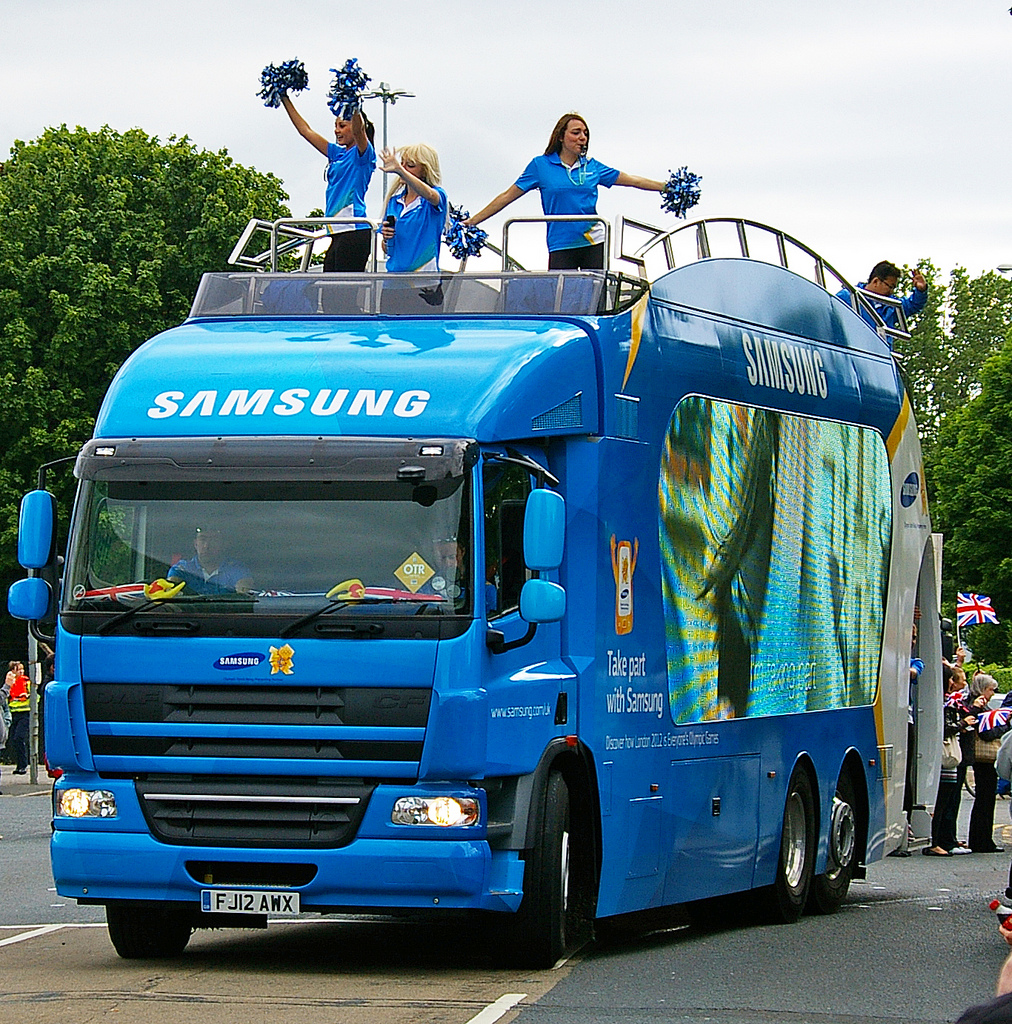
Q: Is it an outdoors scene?
A: Yes, it is outdoors.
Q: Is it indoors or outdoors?
A: It is outdoors.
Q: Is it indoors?
A: No, it is outdoors.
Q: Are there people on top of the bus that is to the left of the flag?
A: Yes, there is a person on top of the bus.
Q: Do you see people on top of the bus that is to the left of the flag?
A: Yes, there is a person on top of the bus.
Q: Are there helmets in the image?
A: No, there are no helmets.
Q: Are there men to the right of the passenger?
A: Yes, there is a man to the right of the passenger.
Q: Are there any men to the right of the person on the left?
A: Yes, there is a man to the right of the passenger.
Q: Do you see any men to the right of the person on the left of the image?
A: Yes, there is a man to the right of the passenger.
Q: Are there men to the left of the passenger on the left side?
A: No, the man is to the right of the passenger.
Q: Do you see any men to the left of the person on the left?
A: No, the man is to the right of the passenger.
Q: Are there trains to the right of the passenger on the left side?
A: No, there is a man to the right of the passenger.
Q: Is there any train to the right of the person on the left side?
A: No, there is a man to the right of the passenger.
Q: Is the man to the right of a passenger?
A: Yes, the man is to the right of a passenger.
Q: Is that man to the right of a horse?
A: No, the man is to the right of a passenger.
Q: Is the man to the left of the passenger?
A: No, the man is to the right of the passenger.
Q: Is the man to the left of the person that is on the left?
A: No, the man is to the right of the passenger.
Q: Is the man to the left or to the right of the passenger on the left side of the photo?
A: The man is to the right of the passenger.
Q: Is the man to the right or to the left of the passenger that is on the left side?
A: The man is to the right of the passenger.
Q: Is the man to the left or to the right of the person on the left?
A: The man is to the right of the passenger.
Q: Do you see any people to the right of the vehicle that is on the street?
A: Yes, there is a person to the right of the bus.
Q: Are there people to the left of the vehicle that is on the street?
A: No, the person is to the right of the bus.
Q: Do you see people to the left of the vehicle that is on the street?
A: No, the person is to the right of the bus.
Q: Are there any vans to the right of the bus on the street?
A: No, there is a person to the right of the bus.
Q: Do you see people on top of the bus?
A: Yes, there is a person on top of the bus.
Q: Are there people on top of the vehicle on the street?
A: Yes, there is a person on top of the bus.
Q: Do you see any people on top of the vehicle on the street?
A: Yes, there is a person on top of the bus.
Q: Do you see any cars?
A: No, there are no cars.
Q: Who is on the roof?
A: The people are on the roof.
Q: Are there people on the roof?
A: Yes, there are people on the roof.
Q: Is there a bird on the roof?
A: No, there are people on the roof.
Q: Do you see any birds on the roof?
A: No, there are people on the roof.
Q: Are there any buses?
A: Yes, there is a bus.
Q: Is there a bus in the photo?
A: Yes, there is a bus.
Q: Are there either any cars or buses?
A: Yes, there is a bus.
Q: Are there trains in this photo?
A: No, there are no trains.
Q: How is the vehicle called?
A: The vehicle is a bus.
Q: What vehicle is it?
A: The vehicle is a bus.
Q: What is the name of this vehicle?
A: This is a bus.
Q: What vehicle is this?
A: This is a bus.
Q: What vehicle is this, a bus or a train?
A: This is a bus.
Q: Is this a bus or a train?
A: This is a bus.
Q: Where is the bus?
A: The bus is on the street.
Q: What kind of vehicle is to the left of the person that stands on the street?
A: The vehicle is a bus.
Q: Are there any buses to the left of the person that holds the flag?
A: Yes, there is a bus to the left of the person.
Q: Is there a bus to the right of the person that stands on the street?
A: No, the bus is to the left of the person.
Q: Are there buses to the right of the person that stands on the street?
A: No, the bus is to the left of the person.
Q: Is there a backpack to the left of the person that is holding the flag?
A: No, there is a bus to the left of the person.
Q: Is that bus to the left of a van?
A: No, the bus is to the left of a person.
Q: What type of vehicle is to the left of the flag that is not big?
A: The vehicle is a bus.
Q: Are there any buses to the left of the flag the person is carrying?
A: Yes, there is a bus to the left of the flag.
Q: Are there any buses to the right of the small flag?
A: No, the bus is to the left of the flag.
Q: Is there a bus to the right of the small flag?
A: No, the bus is to the left of the flag.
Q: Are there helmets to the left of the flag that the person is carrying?
A: No, there is a bus to the left of the flag.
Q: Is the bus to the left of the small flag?
A: Yes, the bus is to the left of the flag.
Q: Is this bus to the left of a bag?
A: No, the bus is to the left of the flag.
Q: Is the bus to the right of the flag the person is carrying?
A: No, the bus is to the left of the flag.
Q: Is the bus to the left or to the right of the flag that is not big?
A: The bus is to the left of the flag.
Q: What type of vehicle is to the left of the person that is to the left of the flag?
A: The vehicle is a bus.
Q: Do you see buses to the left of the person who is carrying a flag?
A: Yes, there is a bus to the left of the person.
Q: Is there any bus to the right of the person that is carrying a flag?
A: No, the bus is to the left of the person.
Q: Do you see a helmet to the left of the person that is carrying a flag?
A: No, there is a bus to the left of the person.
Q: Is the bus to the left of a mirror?
A: No, the bus is to the left of the person.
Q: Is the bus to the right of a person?
A: No, the bus is to the left of a person.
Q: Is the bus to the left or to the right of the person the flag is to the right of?
A: The bus is to the left of the person.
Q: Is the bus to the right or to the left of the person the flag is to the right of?
A: The bus is to the left of the person.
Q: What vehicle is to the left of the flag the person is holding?
A: The vehicle is a bus.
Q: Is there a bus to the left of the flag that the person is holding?
A: Yes, there is a bus to the left of the flag.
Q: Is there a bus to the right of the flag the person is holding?
A: No, the bus is to the left of the flag.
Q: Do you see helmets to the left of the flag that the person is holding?
A: No, there is a bus to the left of the flag.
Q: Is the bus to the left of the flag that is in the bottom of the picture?
A: Yes, the bus is to the left of the flag.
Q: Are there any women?
A: Yes, there is a woman.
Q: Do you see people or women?
A: Yes, there is a woman.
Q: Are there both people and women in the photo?
A: Yes, there are both a woman and a person.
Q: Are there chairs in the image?
A: No, there are no chairs.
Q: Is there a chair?
A: No, there are no chairs.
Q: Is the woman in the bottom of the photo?
A: No, the woman is in the top of the image.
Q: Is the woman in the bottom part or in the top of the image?
A: The woman is in the top of the image.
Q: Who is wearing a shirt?
A: The woman is wearing a shirt.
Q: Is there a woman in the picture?
A: Yes, there is a woman.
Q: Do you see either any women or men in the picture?
A: Yes, there is a woman.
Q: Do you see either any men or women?
A: Yes, there is a woman.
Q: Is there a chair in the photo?
A: No, there are no chairs.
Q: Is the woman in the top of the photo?
A: Yes, the woman is in the top of the image.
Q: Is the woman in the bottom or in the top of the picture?
A: The woman is in the top of the image.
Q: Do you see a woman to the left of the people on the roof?
A: Yes, there is a woman to the left of the people.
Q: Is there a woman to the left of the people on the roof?
A: Yes, there is a woman to the left of the people.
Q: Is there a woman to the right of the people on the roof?
A: No, the woman is to the left of the people.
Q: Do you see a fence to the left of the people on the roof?
A: No, there is a woman to the left of the people.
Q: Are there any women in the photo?
A: Yes, there is a woman.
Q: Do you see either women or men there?
A: Yes, there is a woman.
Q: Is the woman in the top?
A: Yes, the woman is in the top of the image.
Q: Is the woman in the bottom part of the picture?
A: No, the woman is in the top of the image.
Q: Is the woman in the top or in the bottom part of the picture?
A: The woman is in the top of the image.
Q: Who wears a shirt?
A: The woman wears a shirt.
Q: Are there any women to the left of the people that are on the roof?
A: Yes, there is a woman to the left of the people.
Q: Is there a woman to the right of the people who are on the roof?
A: No, the woman is to the left of the people.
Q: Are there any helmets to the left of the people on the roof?
A: No, there is a woman to the left of the people.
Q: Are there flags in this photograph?
A: Yes, there is a flag.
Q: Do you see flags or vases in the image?
A: Yes, there is a flag.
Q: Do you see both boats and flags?
A: No, there is a flag but no boats.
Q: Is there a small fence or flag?
A: Yes, there is a small flag.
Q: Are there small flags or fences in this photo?
A: Yes, there is a small flag.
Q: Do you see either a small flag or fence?
A: Yes, there is a small flag.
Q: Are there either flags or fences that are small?
A: Yes, the flag is small.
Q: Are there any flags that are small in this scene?
A: Yes, there is a small flag.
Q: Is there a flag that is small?
A: Yes, there is a flag that is small.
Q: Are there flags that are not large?
A: Yes, there is a small flag.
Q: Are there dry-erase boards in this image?
A: No, there are no dry-erase boards.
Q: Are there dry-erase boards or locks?
A: No, there are no dry-erase boards or locks.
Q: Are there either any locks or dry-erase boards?
A: No, there are no dry-erase boards or locks.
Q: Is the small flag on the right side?
A: Yes, the flag is on the right of the image.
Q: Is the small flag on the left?
A: No, the flag is on the right of the image.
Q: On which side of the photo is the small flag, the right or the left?
A: The flag is on the right of the image.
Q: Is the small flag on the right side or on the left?
A: The flag is on the right of the image.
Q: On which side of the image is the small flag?
A: The flag is on the right of the image.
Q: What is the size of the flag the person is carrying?
A: The flag is small.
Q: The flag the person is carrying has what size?
A: The flag is small.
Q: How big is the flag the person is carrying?
A: The flag is small.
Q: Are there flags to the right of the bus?
A: Yes, there is a flag to the right of the bus.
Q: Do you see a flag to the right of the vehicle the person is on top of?
A: Yes, there is a flag to the right of the bus.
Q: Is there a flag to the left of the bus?
A: No, the flag is to the right of the bus.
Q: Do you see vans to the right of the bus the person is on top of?
A: No, there is a flag to the right of the bus.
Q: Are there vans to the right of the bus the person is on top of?
A: No, there is a flag to the right of the bus.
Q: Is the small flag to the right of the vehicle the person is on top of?
A: Yes, the flag is to the right of the bus.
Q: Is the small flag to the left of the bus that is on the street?
A: No, the flag is to the right of the bus.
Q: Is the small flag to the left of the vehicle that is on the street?
A: No, the flag is to the right of the bus.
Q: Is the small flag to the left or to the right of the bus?
A: The flag is to the right of the bus.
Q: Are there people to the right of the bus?
A: Yes, there is a person to the right of the bus.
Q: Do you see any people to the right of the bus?
A: Yes, there is a person to the right of the bus.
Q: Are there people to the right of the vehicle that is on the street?
A: Yes, there is a person to the right of the bus.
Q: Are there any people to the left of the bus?
A: No, the person is to the right of the bus.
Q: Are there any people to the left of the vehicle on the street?
A: No, the person is to the right of the bus.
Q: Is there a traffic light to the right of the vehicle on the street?
A: No, there is a person to the right of the bus.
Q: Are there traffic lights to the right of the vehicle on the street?
A: No, there is a person to the right of the bus.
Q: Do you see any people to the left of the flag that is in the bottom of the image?
A: Yes, there is a person to the left of the flag.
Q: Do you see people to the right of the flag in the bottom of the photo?
A: No, the person is to the left of the flag.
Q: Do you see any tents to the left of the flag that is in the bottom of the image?
A: No, there is a person to the left of the flag.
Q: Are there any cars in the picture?
A: No, there are no cars.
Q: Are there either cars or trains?
A: No, there are no cars or trains.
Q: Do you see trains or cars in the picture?
A: No, there are no cars or trains.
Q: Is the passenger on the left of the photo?
A: Yes, the passenger is on the left of the image.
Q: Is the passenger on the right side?
A: No, the passenger is on the left of the image.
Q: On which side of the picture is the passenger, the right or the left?
A: The passenger is on the left of the image.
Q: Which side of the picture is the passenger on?
A: The passenger is on the left of the image.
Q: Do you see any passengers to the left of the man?
A: Yes, there is a passenger to the left of the man.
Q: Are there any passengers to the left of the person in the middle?
A: Yes, there is a passenger to the left of the man.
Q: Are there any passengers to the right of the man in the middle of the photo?
A: No, the passenger is to the left of the man.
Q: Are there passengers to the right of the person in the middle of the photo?
A: No, the passenger is to the left of the man.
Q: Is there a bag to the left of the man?
A: No, there is a passenger to the left of the man.